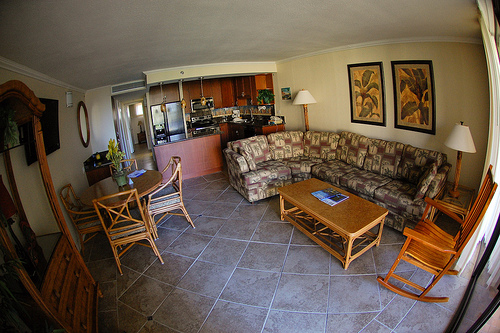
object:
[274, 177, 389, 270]
table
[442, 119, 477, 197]
lamp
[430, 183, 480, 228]
table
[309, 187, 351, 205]
book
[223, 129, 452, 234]
couch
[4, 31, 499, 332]
room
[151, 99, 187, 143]
refrigerator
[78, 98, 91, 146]
mirror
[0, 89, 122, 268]
wall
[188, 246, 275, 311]
floor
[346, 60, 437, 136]
paintings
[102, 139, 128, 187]
plant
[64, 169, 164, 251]
table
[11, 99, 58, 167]
tv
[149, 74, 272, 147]
kitchen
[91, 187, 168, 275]
chair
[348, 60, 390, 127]
palm tree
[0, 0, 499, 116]
air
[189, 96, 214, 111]
microwave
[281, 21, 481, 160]
wall